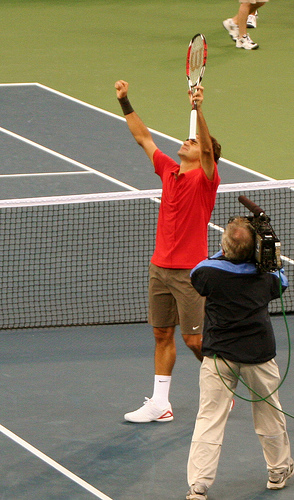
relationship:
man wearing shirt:
[112, 78, 234, 428] [148, 146, 220, 269]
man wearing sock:
[112, 78, 234, 428] [146, 373, 174, 405]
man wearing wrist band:
[112, 78, 234, 428] [117, 98, 133, 116]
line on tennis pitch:
[1, 126, 141, 193] [1, 82, 291, 499]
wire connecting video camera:
[208, 270, 290, 420] [229, 190, 280, 262]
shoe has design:
[123, 401, 182, 424] [156, 411, 173, 421]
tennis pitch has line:
[1, 82, 291, 499] [1, 126, 141, 193]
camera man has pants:
[175, 220, 290, 499] [187, 355, 291, 494]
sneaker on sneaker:
[222, 19, 240, 40] [222, 19, 240, 40]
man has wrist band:
[112, 78, 234, 428] [117, 98, 133, 116]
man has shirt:
[112, 78, 234, 428] [148, 146, 220, 269]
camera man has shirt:
[175, 220, 290, 499] [188, 254, 290, 363]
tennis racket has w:
[181, 26, 204, 142] [188, 48, 202, 69]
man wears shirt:
[112, 78, 234, 428] [148, 146, 220, 269]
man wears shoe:
[112, 78, 234, 428] [123, 401, 182, 424]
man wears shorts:
[112, 78, 234, 428] [146, 267, 206, 336]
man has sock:
[112, 78, 234, 428] [146, 373, 174, 405]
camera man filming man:
[175, 220, 290, 499] [112, 78, 234, 428]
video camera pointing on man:
[229, 190, 280, 262] [112, 78, 234, 428]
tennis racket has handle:
[181, 26, 204, 142] [188, 86, 204, 141]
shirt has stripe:
[188, 254, 290, 363] [187, 257, 289, 289]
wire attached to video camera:
[208, 270, 290, 420] [229, 190, 280, 262]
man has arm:
[112, 78, 234, 428] [118, 98, 172, 169]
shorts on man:
[146, 267, 206, 336] [112, 78, 234, 428]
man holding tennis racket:
[112, 78, 234, 428] [181, 26, 204, 142]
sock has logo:
[146, 373, 174, 405] [157, 378, 170, 386]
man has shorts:
[112, 78, 234, 428] [146, 267, 206, 336]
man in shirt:
[112, 78, 234, 428] [148, 146, 220, 269]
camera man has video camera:
[175, 220, 290, 499] [229, 190, 280, 262]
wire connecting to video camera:
[208, 270, 290, 420] [229, 190, 280, 262]